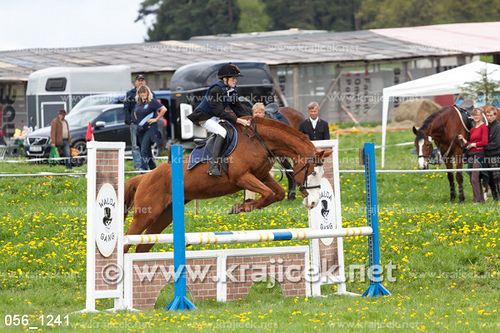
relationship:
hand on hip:
[147, 114, 158, 124] [147, 120, 162, 132]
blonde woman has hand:
[129, 85, 166, 170] [147, 114, 158, 124]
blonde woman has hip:
[129, 85, 166, 170] [147, 120, 162, 132]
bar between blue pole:
[184, 220, 366, 242] [163, 144, 198, 312]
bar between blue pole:
[184, 220, 366, 242] [361, 142, 392, 298]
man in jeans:
[290, 87, 347, 155] [182, 110, 241, 167]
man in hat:
[290, 87, 347, 155] [202, 54, 250, 81]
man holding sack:
[45, 106, 73, 163] [43, 140, 62, 170]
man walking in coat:
[45, 106, 73, 163] [45, 111, 75, 149]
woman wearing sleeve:
[459, 107, 491, 199] [478, 120, 485, 147]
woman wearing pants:
[459, 107, 491, 199] [466, 153, 483, 198]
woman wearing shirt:
[459, 107, 491, 199] [468, 124, 490, 152]